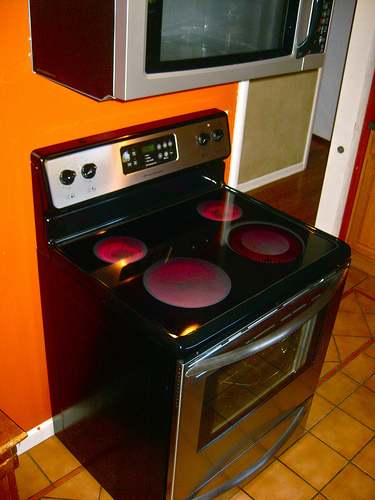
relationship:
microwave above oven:
[19, 1, 344, 106] [15, 102, 366, 499]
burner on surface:
[192, 190, 251, 230] [39, 156, 360, 362]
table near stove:
[2, 404, 42, 499] [15, 102, 366, 499]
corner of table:
[0, 406, 30, 461] [2, 404, 42, 499]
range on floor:
[15, 102, 366, 499] [0, 251, 373, 499]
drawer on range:
[149, 390, 313, 499] [15, 102, 366, 499]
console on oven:
[106, 131, 200, 173] [15, 102, 366, 499]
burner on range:
[192, 190, 251, 230] [15, 102, 366, 499]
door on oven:
[166, 274, 351, 499] [15, 102, 366, 499]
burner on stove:
[192, 190, 251, 230] [15, 102, 366, 499]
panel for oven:
[26, 103, 262, 230] [15, 102, 366, 499]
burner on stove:
[136, 252, 240, 317] [15, 102, 366, 499]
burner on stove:
[218, 216, 315, 271] [15, 102, 366, 499]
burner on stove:
[80, 227, 153, 269] [15, 102, 366, 499]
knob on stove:
[58, 168, 80, 189] [15, 102, 366, 499]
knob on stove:
[78, 162, 100, 183] [15, 102, 366, 499]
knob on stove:
[191, 128, 219, 148] [15, 102, 366, 499]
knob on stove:
[210, 122, 223, 143] [15, 102, 366, 499]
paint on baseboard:
[32, 424, 44, 437] [11, 410, 56, 454]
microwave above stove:
[19, 1, 344, 106] [15, 102, 366, 499]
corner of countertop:
[0, 406, 30, 461] [2, 404, 42, 499]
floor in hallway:
[238, 127, 320, 226] [235, 0, 323, 228]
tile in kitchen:
[0, 251, 373, 499] [4, 6, 362, 487]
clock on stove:
[137, 140, 160, 156] [15, 102, 366, 499]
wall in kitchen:
[2, 3, 51, 450] [4, 6, 362, 487]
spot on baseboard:
[32, 424, 44, 431] [11, 410, 56, 454]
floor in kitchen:
[0, 251, 373, 499] [4, 6, 362, 487]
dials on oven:
[49, 162, 102, 189] [15, 102, 366, 499]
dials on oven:
[193, 125, 230, 147] [15, 102, 366, 499]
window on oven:
[198, 317, 320, 442] [15, 102, 366, 499]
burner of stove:
[192, 190, 251, 230] [15, 102, 366, 499]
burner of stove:
[136, 252, 240, 317] [15, 102, 366, 499]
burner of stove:
[218, 216, 315, 271] [15, 102, 366, 499]